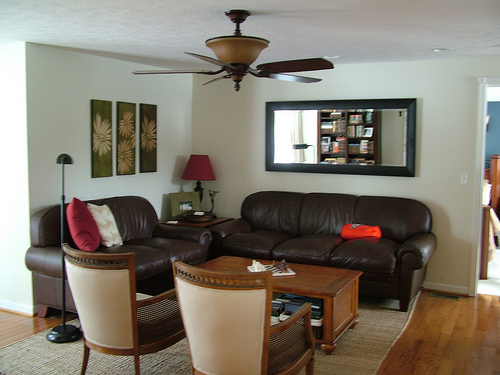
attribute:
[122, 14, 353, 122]
fan — wooden 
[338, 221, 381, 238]
bag — bright red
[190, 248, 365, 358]
coffee table — Wooden 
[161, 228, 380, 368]
table — wooden 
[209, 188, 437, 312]
brown sofa —  dark brown ,  leather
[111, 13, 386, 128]
fan — brown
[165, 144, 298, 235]
lamp — red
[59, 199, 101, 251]
pillow — red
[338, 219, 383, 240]
cloth — red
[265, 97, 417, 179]
mirror — framed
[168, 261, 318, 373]
chair — wooden , Cushioned 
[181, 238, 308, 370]
chair — wooden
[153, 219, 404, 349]
coffee table — brown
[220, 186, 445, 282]
sofa — leather, dark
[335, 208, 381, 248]
bag — red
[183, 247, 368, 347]
coffee table — Wooden 